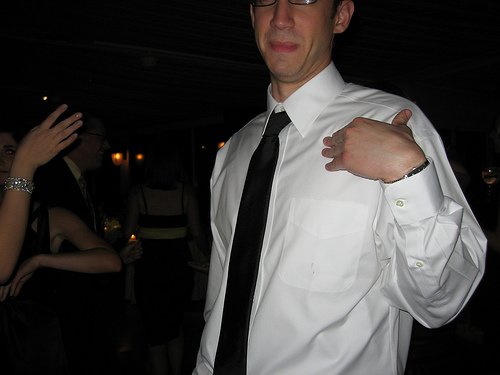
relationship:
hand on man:
[9, 102, 84, 170] [203, 0, 481, 374]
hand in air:
[9, 102, 84, 170] [7, 3, 492, 364]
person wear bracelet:
[0, 103, 126, 305] [0, 172, 36, 194]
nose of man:
[268, 1, 293, 28] [190, 0, 488, 374]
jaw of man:
[261, 59, 306, 83] [190, 0, 488, 374]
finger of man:
[315, 129, 341, 146] [190, 0, 488, 374]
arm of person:
[320, 99, 486, 333] [2, 128, 125, 298]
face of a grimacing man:
[242, 1, 354, 89] [203, 0, 481, 374]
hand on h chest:
[320, 106, 427, 182] [214, 106, 389, 337]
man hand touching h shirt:
[203, 0, 481, 374] [194, 57, 487, 372]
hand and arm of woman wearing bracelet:
[14, 102, 84, 167] [5, 175, 35, 195]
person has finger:
[0, 103, 126, 305] [41, 102, 67, 127]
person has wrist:
[14, 31, 70, 343] [7, 169, 29, 198]